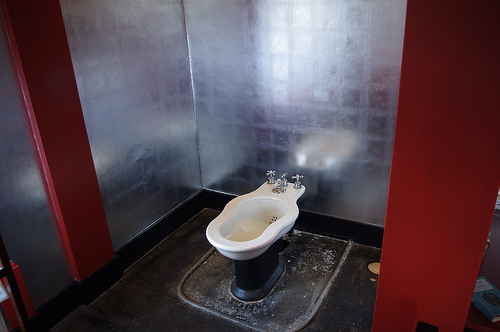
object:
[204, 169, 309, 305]
toilet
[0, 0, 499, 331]
bathroom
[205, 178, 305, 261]
upper piece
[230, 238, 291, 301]
base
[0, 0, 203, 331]
walls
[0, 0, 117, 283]
plank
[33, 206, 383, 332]
floor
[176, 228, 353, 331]
bottom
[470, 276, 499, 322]
book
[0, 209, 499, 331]
ground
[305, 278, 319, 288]
specks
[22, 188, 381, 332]
baseboard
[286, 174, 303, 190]
faucets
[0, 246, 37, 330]
pipe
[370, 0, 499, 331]
stall divider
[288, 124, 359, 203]
reflection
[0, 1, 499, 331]
patterns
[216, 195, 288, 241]
interior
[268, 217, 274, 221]
holes